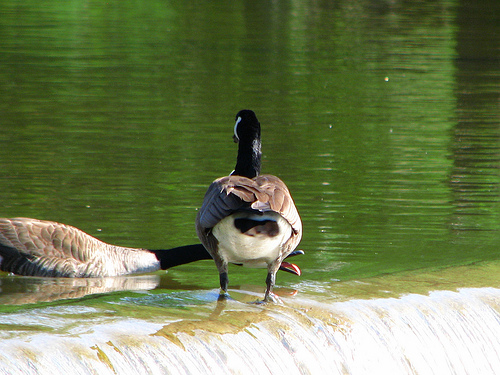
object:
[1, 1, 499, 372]
water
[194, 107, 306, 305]
duck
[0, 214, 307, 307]
geese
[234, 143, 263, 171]
neck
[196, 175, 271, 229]
feathers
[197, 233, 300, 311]
goose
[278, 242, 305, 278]
mouth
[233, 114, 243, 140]
mark